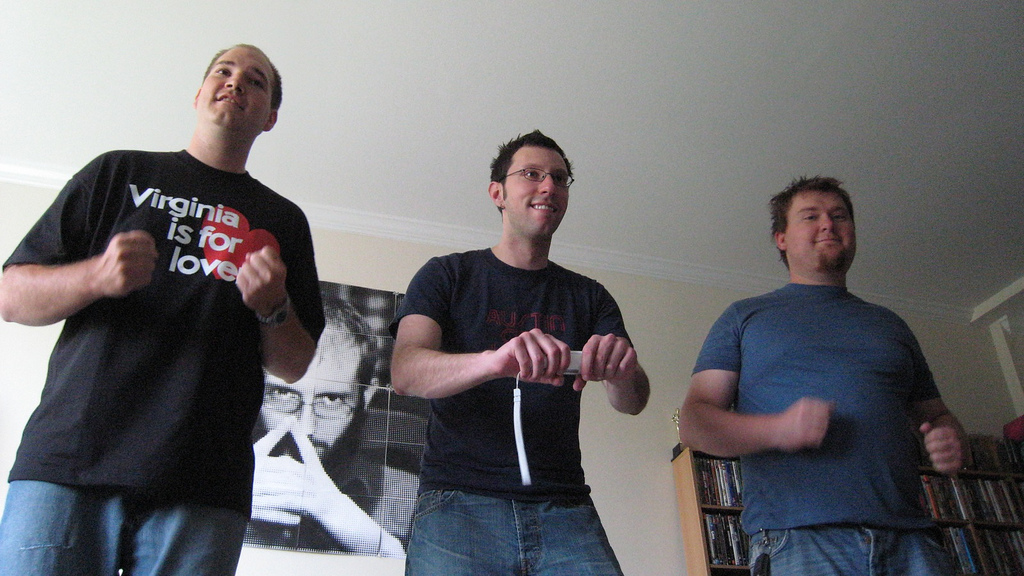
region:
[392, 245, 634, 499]
a men's black printed t-shirt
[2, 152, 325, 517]
a men's black printed t-shirt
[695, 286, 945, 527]
a men's blue t-shirt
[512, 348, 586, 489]
a white Wii remote game controller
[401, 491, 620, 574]
a pair of blue jeans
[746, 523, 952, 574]
a pair of blue jeans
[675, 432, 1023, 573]
a brown wooden bookcase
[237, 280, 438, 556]
a black and white print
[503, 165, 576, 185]
a pair of eyeglasses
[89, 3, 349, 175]
head of a man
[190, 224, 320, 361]
fist of the man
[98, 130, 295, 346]
writing on the shirt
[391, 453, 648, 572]
blue pants on man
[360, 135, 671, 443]
man wearing pair of glasses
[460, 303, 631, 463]
remote in man's hand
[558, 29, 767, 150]
roof of the room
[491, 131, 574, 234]
man has a white head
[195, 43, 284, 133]
man has a white head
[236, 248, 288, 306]
man has a white hand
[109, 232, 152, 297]
man has a white hand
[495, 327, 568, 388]
man has a white hand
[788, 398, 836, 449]
man has a white hand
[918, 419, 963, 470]
man has a white hand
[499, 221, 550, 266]
man has a neck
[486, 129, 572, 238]
white man has a head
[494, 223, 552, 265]
white man has a neck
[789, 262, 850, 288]
white man has a neck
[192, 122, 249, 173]
white man has a neck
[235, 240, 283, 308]
white man has a hand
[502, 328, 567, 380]
white man has a hand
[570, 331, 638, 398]
white man has a hand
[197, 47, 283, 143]
white man has a head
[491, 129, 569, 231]
white man has a head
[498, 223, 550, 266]
white man has a neck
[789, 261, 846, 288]
white man has a neck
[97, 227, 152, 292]
white man has a hand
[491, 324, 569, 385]
white man has a hand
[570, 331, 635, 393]
white man has a hand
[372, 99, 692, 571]
a man who is playing wiii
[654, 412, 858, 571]
a bookshelf which is block by a man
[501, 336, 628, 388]
a white wii remote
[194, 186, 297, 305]
a red heart on a shirt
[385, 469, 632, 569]
a pair of blue jeans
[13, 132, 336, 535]
Man wearing a black shirt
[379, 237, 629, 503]
Man wearing a black shirt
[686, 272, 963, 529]
man wearing a blue shirt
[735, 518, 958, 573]
man wearing blue jeans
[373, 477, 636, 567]
man wearing blue jeans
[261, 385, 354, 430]
man wearing reading glasses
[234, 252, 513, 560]
picture hanging on the wall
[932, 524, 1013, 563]
books on the shelf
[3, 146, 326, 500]
the shirt is black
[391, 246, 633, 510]
the shirt is dark blue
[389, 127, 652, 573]
the man is wearing glasses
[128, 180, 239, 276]
the letters are white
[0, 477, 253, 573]
the pants are blue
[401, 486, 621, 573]
the jeans are blue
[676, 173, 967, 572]
the man is wearing a blue shirt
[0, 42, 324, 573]
the man is wearing a black shirt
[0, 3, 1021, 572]
the men are standing